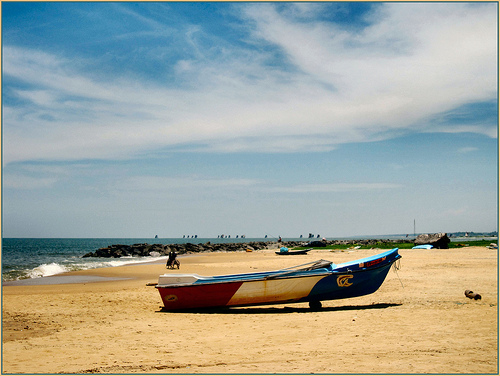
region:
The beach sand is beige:
[46, 323, 488, 369]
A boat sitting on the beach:
[148, 242, 411, 317]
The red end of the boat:
[147, 263, 234, 315]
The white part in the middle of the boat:
[232, 264, 318, 315]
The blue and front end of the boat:
[323, 244, 405, 303]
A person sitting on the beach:
[160, 239, 192, 273]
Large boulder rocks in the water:
[72, 236, 287, 256]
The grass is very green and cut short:
[299, 239, 421, 250]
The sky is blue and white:
[58, 164, 493, 219]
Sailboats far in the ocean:
[144, 220, 331, 241]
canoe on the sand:
[146, 227, 412, 345]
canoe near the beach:
[36, 200, 472, 365]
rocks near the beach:
[73, 218, 276, 264]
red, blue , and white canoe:
[142, 235, 417, 327]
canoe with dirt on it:
[136, 238, 412, 329]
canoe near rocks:
[75, 223, 415, 329]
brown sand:
[168, 313, 403, 375]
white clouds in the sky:
[3, 1, 494, 209]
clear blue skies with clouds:
[6, 2, 492, 232]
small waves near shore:
[0, 244, 171, 291]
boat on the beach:
[136, 238, 413, 320]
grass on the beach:
[330, 233, 491, 258]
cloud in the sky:
[0, 70, 490, 180]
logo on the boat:
[332, 267, 352, 287]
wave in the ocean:
[15, 240, 70, 300]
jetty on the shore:
[71, 235, 317, 271]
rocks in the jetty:
[80, 230, 225, 265]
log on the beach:
[457, 285, 482, 300]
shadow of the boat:
[205, 295, 405, 325]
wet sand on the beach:
[0, 305, 71, 355]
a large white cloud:
[3, 0, 496, 180]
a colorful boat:
[148, 246, 406, 318]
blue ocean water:
[4, 235, 144, 274]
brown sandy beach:
[0, 243, 498, 375]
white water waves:
[31, 258, 63, 275]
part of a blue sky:
[257, 154, 347, 174]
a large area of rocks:
[85, 239, 186, 259]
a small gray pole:
[410, 216, 416, 234]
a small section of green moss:
[2, 262, 22, 282]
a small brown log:
[465, 291, 480, 301]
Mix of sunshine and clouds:
[4, 3, 499, 199]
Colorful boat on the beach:
[147, 244, 407, 314]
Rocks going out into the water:
[79, 228, 466, 259]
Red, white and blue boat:
[148, 248, 409, 314]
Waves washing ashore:
[15, 240, 190, 292]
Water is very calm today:
[3, 233, 258, 260]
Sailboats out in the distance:
[151, 231, 339, 241]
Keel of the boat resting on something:
[306, 295, 327, 313]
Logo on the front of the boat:
[334, 270, 356, 290]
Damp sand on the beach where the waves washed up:
[4, 259, 150, 294]